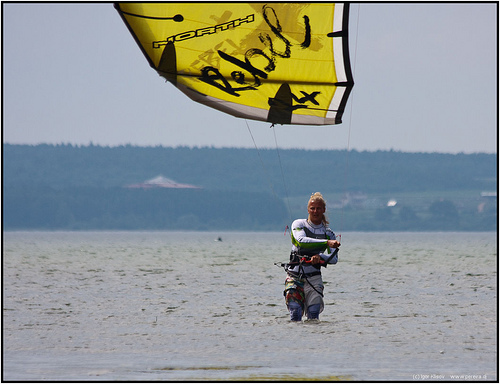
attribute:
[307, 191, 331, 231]
hair — blonde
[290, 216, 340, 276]
shirt — green, blue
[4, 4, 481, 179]
sky — blue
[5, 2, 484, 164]
sky — blue, hazy, cold, ocean sky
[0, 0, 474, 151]
sky — blue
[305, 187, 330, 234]
hair — long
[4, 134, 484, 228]
hill — covered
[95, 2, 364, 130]
parachute — yellow, black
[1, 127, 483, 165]
horizon — trees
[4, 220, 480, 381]
water — grey, mulky, thick, choppy, cold, ocean water, blue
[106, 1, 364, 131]
parasail — yellow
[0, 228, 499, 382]
beach — sandy, beige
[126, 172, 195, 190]
surf — white, churning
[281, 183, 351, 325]
woman — blonde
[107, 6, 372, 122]
sail — white, black, yellow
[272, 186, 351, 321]
person — happy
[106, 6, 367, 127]
kite — bright yellow, black, yellow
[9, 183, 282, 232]
hill — land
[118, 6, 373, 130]
yellow — black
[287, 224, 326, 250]
white sleeve — white 